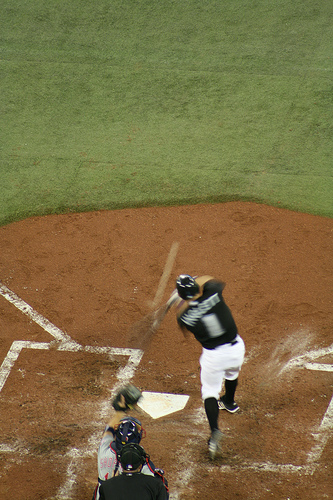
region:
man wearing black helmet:
[170, 271, 201, 300]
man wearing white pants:
[201, 365, 221, 395]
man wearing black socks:
[200, 396, 225, 426]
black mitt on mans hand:
[118, 384, 139, 412]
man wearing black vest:
[109, 481, 129, 495]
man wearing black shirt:
[221, 309, 231, 324]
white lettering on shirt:
[176, 311, 224, 320]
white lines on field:
[80, 342, 143, 360]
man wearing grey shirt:
[103, 447, 109, 472]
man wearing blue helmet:
[120, 418, 136, 438]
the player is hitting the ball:
[138, 244, 260, 452]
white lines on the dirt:
[241, 313, 330, 480]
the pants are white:
[176, 330, 244, 398]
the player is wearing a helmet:
[160, 264, 204, 307]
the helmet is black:
[153, 264, 205, 303]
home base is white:
[117, 373, 190, 421]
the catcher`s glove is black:
[77, 374, 148, 418]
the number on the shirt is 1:
[159, 268, 253, 346]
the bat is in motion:
[143, 254, 256, 349]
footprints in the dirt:
[67, 213, 289, 293]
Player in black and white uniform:
[124, 269, 254, 460]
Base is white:
[124, 383, 190, 424]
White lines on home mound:
[0, 204, 331, 497]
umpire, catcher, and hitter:
[90, 268, 261, 497]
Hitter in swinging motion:
[126, 268, 243, 458]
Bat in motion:
[124, 292, 180, 354]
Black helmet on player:
[170, 272, 206, 304]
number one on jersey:
[184, 307, 236, 348]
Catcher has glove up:
[98, 378, 150, 474]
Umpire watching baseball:
[95, 442, 169, 498]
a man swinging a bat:
[129, 262, 253, 467]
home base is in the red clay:
[135, 384, 191, 425]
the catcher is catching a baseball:
[96, 381, 168, 447]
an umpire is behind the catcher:
[95, 442, 169, 498]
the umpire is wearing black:
[96, 444, 170, 497]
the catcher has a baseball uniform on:
[92, 415, 156, 475]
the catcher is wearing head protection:
[114, 414, 144, 444]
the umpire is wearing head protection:
[117, 440, 147, 472]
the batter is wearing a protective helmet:
[174, 271, 200, 302]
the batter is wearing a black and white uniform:
[170, 279, 249, 436]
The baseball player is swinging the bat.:
[122, 240, 249, 422]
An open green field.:
[43, 19, 275, 165]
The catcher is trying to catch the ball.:
[100, 373, 187, 478]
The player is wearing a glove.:
[102, 357, 151, 421]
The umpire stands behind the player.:
[102, 432, 163, 499]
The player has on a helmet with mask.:
[116, 413, 148, 444]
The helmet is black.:
[157, 260, 211, 299]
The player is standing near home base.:
[125, 368, 202, 427]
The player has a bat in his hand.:
[136, 280, 184, 324]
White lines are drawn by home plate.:
[11, 277, 172, 407]